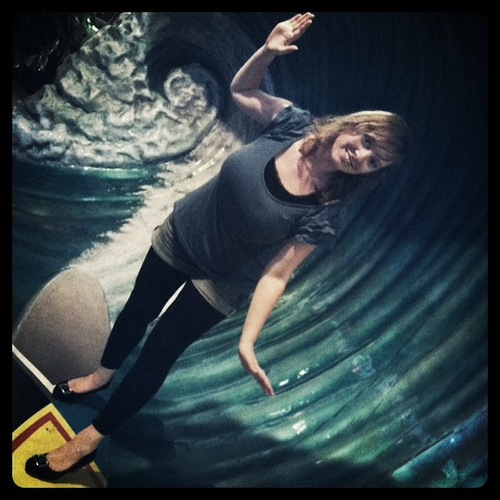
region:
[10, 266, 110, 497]
the surfboard on the ground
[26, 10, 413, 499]
the woman pretending to surf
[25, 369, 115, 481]
the shoes on the woman's feet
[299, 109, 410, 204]
the hair on the woman's head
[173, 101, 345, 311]
the woman's short sleeved shirt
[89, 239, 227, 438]
the woman's black pants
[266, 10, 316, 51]
the woman's hand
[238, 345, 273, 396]
the woman's hand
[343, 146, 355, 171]
the smile on the woman's face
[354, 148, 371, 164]
the nose on the woman's face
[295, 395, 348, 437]
Fake blue water that the lady is surfing on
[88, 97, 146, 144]
Fake white waves in the background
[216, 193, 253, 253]
Gray shirt of the lady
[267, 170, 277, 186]
Black undershirt of the female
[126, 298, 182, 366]
Black pants of the female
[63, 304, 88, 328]
Gray part of the surfboard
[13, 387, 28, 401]
Black part of the surfboard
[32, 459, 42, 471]
Left black heels of the female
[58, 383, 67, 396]
Right black heels of lady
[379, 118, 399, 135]
Blonde hair of the female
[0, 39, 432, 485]
woman posing for photo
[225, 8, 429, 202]
hand raised above head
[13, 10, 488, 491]
painted illusion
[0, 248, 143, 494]
surfboard painted on floor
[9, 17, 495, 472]
waves painted on floor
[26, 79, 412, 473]
woman wearing black leggings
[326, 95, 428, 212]
woman smiling at camera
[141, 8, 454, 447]
woman wearing grey and black shirts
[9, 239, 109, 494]
multi colored painted surfboard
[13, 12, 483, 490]
optical illusion painted on floor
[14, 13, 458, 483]
a woman inside of a tube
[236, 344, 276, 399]
the hand of a woman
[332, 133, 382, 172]
the face of a woman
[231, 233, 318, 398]
the arm of a woman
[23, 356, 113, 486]
the feet of a woman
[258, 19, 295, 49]
the palm of a woman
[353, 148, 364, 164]
the nose of a woman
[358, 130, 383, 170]
the eyes of a woman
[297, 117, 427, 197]
a woman with blonde hair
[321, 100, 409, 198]
a woman who is smiling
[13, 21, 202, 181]
A scary dark tunnel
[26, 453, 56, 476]
Shiny low heeled shoe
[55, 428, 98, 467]
A clean white leg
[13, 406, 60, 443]
Yellow and brown mat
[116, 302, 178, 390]
Black tight fitting pants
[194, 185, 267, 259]
A dark grey vest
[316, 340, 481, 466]
A low lying tank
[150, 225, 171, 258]
A short grey short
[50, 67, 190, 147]
Hard textured grey rocks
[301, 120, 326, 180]
Long flowing brown hair